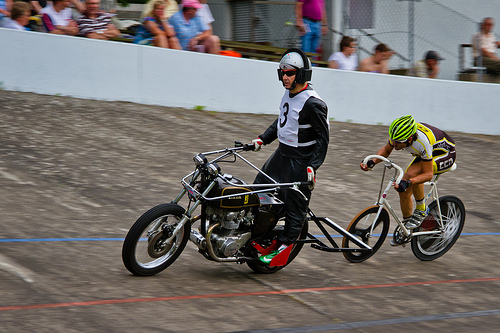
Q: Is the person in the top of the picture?
A: Yes, the person is in the top of the image.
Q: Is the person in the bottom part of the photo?
A: No, the person is in the top of the image.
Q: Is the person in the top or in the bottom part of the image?
A: The person is in the top of the image.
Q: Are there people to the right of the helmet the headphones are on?
A: Yes, there is a person to the right of the helmet.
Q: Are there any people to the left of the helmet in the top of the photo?
A: No, the person is to the right of the helmet.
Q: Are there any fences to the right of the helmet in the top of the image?
A: No, there is a person to the right of the helmet.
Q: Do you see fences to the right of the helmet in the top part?
A: No, there is a person to the right of the helmet.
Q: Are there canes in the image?
A: No, there are no canes.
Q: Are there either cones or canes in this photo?
A: No, there are no canes or cones.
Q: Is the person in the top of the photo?
A: Yes, the person is in the top of the image.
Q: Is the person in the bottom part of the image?
A: No, the person is in the top of the image.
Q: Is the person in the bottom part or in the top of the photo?
A: The person is in the top of the image.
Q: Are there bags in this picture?
A: No, there are no bags.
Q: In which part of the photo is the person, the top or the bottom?
A: The person is in the top of the image.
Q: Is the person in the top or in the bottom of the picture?
A: The person is in the top of the image.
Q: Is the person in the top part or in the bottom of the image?
A: The person is in the top of the image.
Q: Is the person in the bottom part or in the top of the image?
A: The person is in the top of the image.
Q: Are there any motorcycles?
A: Yes, there is a motorcycle.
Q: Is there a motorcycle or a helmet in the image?
A: Yes, there is a motorcycle.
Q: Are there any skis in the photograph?
A: No, there are no skis.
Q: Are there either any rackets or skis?
A: No, there are no skis or rackets.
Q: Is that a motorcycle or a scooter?
A: That is a motorcycle.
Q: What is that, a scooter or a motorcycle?
A: That is a motorcycle.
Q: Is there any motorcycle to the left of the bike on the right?
A: Yes, there is a motorcycle to the left of the bike.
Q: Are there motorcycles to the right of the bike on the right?
A: No, the motorcycle is to the left of the bike.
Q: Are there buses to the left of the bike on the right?
A: No, there is a motorcycle to the left of the bike.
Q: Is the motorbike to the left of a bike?
A: Yes, the motorbike is to the left of a bike.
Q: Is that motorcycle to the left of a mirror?
A: No, the motorcycle is to the left of a bike.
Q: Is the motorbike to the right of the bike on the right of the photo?
A: No, the motorbike is to the left of the bike.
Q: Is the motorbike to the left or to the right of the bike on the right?
A: The motorbike is to the left of the bike.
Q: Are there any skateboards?
A: No, there are no skateboards.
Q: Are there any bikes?
A: Yes, there is a bike.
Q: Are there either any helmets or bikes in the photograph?
A: Yes, there is a bike.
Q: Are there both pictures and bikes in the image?
A: No, there is a bike but no pictures.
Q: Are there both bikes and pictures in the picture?
A: No, there is a bike but no pictures.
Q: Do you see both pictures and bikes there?
A: No, there is a bike but no pictures.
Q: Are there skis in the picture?
A: No, there are no skis.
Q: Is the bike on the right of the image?
A: Yes, the bike is on the right of the image.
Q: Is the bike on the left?
A: No, the bike is on the right of the image.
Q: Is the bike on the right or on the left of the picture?
A: The bike is on the right of the image.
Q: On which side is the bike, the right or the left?
A: The bike is on the right of the image.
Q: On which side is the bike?
A: The bike is on the right of the image.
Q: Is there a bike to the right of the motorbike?
A: Yes, there is a bike to the right of the motorbike.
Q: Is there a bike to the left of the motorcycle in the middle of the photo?
A: No, the bike is to the right of the motorcycle.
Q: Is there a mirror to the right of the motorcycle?
A: No, there is a bike to the right of the motorcycle.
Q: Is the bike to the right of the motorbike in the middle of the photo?
A: Yes, the bike is to the right of the motorcycle.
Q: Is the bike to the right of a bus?
A: No, the bike is to the right of the motorcycle.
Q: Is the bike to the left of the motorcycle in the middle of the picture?
A: No, the bike is to the right of the motorbike.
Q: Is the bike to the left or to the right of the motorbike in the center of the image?
A: The bike is to the right of the motorbike.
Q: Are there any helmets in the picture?
A: Yes, there is a helmet.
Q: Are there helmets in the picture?
A: Yes, there is a helmet.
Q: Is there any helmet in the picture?
A: Yes, there is a helmet.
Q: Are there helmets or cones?
A: Yes, there is a helmet.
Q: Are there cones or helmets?
A: Yes, there is a helmet.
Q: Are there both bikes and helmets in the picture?
A: Yes, there are both a helmet and a bike.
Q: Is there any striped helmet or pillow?
A: Yes, there is a striped helmet.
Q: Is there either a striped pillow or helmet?
A: Yes, there is a striped helmet.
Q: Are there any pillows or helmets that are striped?
A: Yes, the helmet is striped.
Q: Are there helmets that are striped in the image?
A: Yes, there is a striped helmet.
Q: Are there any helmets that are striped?
A: Yes, there is a helmet that is striped.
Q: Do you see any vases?
A: No, there are no vases.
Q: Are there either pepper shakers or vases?
A: No, there are no vases or pepper shakers.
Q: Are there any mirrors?
A: No, there are no mirrors.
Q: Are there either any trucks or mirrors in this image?
A: No, there are no mirrors or trucks.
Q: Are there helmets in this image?
A: Yes, there is a helmet.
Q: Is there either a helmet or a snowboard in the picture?
A: Yes, there is a helmet.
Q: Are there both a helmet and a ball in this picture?
A: No, there is a helmet but no balls.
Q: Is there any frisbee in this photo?
A: No, there are no frisbees.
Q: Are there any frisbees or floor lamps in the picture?
A: No, there are no frisbees or floor lamps.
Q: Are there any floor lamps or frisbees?
A: No, there are no frisbees or floor lamps.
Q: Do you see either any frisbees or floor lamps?
A: No, there are no frisbees or floor lamps.